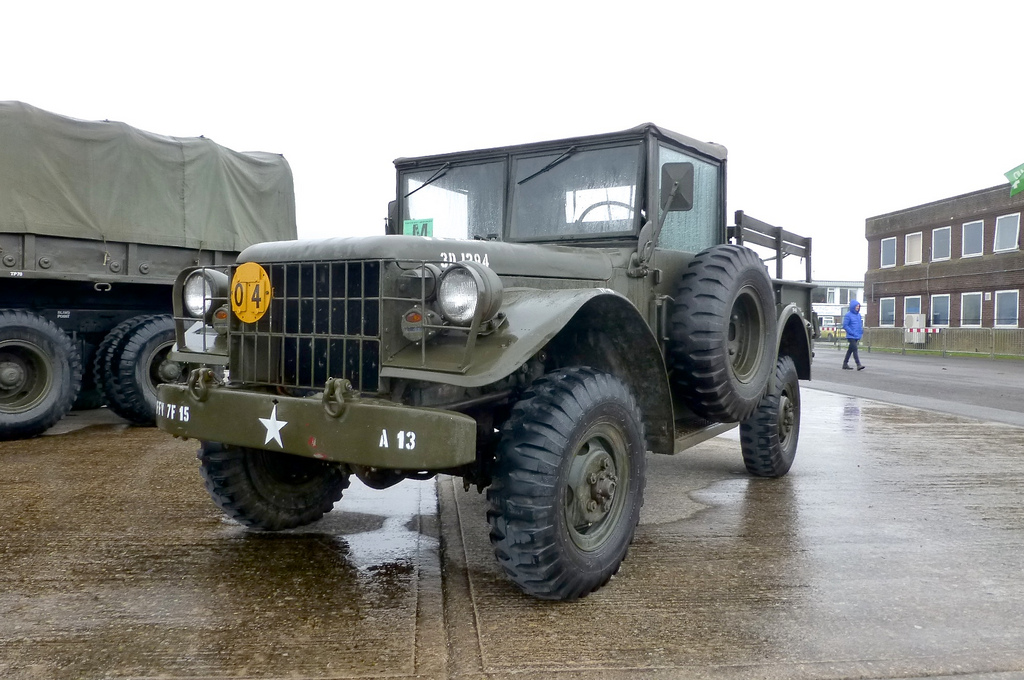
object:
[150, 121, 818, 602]
army jeep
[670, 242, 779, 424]
tire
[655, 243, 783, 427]
door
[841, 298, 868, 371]
person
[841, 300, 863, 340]
jacket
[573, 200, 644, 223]
steering wheel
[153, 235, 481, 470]
front grill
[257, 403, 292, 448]
star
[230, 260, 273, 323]
circle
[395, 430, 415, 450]
numbers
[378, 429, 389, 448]
letters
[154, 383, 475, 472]
bumper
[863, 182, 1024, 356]
brick building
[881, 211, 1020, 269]
windows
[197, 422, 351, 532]
wheel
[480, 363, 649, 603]
wheel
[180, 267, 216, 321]
headlight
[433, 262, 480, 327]
headlight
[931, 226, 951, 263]
window